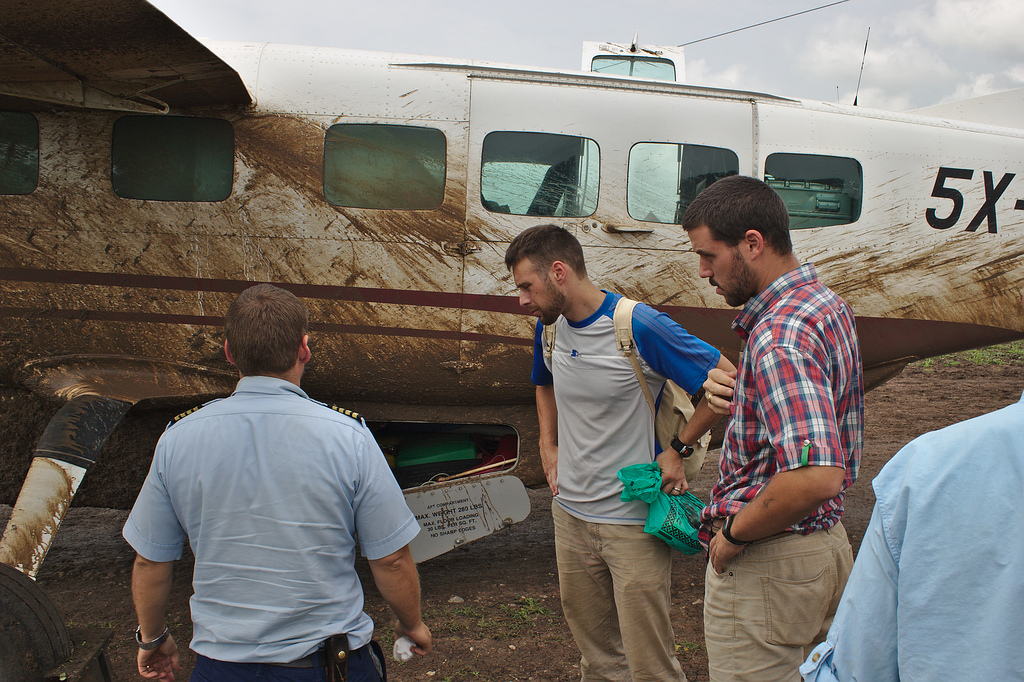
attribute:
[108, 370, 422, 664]
uniform — blue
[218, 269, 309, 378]
hair — brown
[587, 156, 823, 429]
man — young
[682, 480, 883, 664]
pants — brown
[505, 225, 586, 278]
hair — clean cut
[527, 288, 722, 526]
shirt — gray, blue, WHITE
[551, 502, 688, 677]
pants — brown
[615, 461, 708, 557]
bag — blue, plastic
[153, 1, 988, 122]
sky — daytime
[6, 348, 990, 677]
surface — dirt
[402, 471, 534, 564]
door — open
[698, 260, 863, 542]
shirt — plaid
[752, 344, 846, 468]
sleeves — short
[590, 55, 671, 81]
glass — CLEAN, CLEAR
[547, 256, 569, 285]
ear — WHITE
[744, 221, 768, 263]
ear — WHITE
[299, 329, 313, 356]
ear — WHITE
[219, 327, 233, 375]
ear — WHITE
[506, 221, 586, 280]
hair — DARK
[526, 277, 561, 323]
hair — FACIAL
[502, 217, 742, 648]
man — WEARING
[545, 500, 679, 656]
pants — KHAKI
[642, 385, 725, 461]
backpack — BEIGE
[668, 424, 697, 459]
watch — BLACK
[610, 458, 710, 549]
bandanna — GREEN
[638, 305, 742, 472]
arms — AKIMBO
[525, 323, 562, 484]
arms — AKIMBO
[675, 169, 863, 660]
man — WEARING